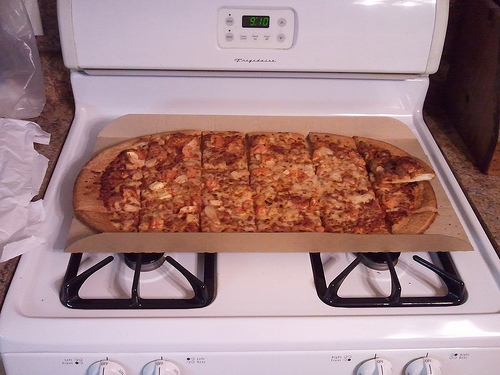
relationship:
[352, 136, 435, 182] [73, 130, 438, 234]
pizza on cheese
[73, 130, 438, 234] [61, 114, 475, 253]
cheese on cardboard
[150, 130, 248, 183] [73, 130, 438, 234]
squares on cheese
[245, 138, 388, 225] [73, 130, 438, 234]
squares on cheese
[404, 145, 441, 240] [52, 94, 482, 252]
crust on pizza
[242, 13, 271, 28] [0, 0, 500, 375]
digital clock on gas stove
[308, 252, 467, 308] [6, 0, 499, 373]
burner on gas stove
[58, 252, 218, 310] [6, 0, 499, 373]
burner on gas stove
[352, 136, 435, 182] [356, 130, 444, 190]
pizza of pizza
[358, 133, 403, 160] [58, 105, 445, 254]
slice of pizza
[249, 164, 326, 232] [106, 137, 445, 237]
pizza slice of pizza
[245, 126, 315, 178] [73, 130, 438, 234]
slice of cheese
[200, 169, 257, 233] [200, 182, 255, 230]
pizza of pizza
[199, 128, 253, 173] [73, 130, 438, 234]
slice of cheese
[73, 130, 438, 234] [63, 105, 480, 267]
cheese sitting on cardboard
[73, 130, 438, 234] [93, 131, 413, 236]
cheese with sauce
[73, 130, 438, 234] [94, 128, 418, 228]
cheese with cheese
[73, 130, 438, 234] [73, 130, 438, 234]
cheese with cheese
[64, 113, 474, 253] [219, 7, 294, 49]
cardboard and buttons